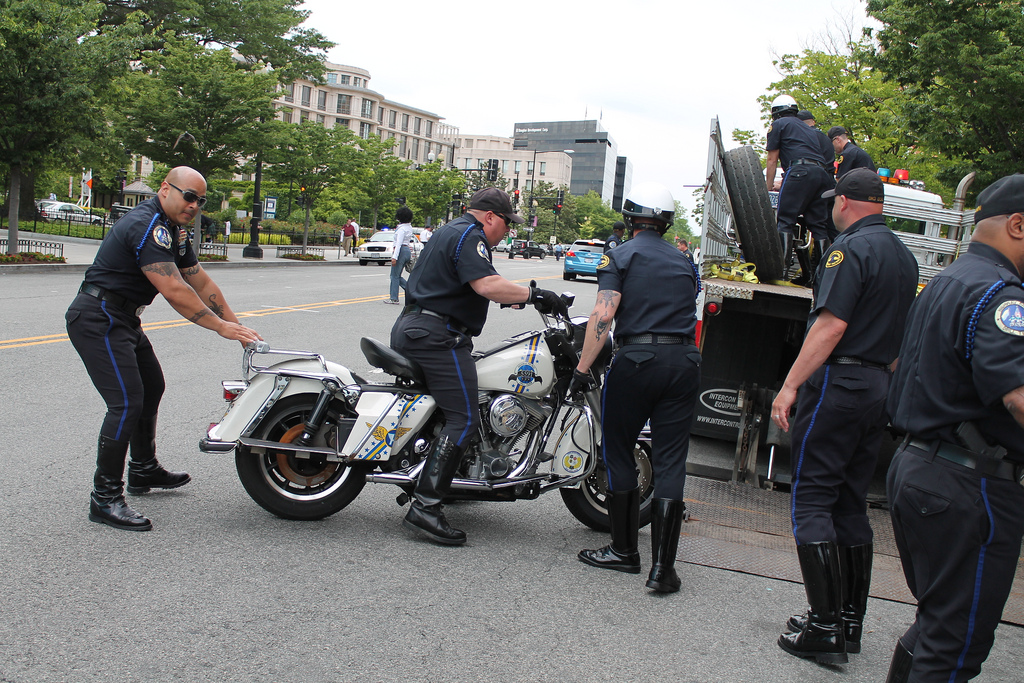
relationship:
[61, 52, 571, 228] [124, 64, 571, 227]
wall on side of a wall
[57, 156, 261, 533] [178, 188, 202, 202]
man wearing sunglasses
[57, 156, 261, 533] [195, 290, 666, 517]
man holding motorcycle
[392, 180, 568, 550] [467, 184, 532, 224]
man in hat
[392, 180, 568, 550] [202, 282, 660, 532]
man sitting on bike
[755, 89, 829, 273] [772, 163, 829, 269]
man in pants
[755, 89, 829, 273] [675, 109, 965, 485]
man standing in back of truck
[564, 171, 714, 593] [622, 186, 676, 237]
man in head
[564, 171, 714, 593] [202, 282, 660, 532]
man touching bike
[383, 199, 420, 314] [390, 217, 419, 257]
woman in shirt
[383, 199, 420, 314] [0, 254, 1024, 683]
woman walking across ground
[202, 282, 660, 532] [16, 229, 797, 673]
bike sitting on ground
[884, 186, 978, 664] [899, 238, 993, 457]
man in shirt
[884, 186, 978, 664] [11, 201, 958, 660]
man standing on street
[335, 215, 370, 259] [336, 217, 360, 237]
person in shirt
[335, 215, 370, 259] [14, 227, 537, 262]
person walking down sidewalk